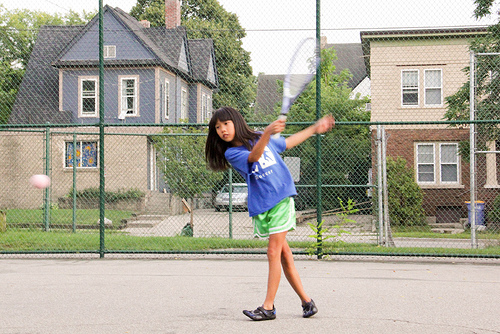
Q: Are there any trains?
A: No, there are no trains.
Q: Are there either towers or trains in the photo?
A: No, there are no trains or towers.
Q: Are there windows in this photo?
A: Yes, there is a window.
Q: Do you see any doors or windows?
A: Yes, there is a window.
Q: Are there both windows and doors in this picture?
A: No, there is a window but no doors.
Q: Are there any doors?
A: No, there are no doors.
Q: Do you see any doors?
A: No, there are no doors.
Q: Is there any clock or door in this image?
A: No, there are no doors or clocks.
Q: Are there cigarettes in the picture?
A: No, there are no cigarettes.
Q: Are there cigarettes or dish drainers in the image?
A: No, there are no cigarettes or dish drainers.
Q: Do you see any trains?
A: No, there are no trains.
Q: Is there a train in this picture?
A: No, there are no trains.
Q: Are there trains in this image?
A: No, there are no trains.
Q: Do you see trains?
A: No, there are no trains.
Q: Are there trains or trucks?
A: No, there are no trains or trucks.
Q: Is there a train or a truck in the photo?
A: No, there are no trains or trucks.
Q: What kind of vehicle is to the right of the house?
A: The vehicle is a car.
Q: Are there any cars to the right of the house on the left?
A: Yes, there is a car to the right of the house.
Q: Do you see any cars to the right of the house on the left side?
A: Yes, there is a car to the right of the house.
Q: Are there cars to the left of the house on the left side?
A: No, the car is to the right of the house.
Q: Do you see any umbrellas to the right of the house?
A: No, there is a car to the right of the house.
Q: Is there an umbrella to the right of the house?
A: No, there is a car to the right of the house.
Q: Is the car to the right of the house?
A: Yes, the car is to the right of the house.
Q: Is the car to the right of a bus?
A: No, the car is to the right of the house.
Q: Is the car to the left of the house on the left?
A: No, the car is to the right of the house.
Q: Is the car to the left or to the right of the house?
A: The car is to the right of the house.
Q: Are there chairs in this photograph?
A: No, there are no chairs.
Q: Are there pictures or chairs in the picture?
A: No, there are no chairs or pictures.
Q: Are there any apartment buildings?
A: No, there are no apartment buildings.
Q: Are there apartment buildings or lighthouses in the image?
A: No, there are no apartment buildings or lighthouses.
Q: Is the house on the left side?
A: Yes, the house is on the left of the image.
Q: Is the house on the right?
A: No, the house is on the left of the image.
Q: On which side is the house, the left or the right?
A: The house is on the left of the image.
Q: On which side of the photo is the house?
A: The house is on the left of the image.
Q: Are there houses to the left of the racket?
A: Yes, there is a house to the left of the racket.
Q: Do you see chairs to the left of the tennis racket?
A: No, there is a house to the left of the tennis racket.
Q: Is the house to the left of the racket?
A: Yes, the house is to the left of the racket.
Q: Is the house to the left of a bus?
A: No, the house is to the left of the racket.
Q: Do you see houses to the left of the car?
A: Yes, there is a house to the left of the car.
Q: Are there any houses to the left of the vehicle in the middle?
A: Yes, there is a house to the left of the car.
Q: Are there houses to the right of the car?
A: No, the house is to the left of the car.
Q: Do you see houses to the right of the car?
A: No, the house is to the left of the car.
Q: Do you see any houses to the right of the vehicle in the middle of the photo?
A: No, the house is to the left of the car.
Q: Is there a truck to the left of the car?
A: No, there is a house to the left of the car.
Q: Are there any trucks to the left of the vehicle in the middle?
A: No, there is a house to the left of the car.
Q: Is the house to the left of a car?
A: Yes, the house is to the left of a car.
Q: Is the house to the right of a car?
A: No, the house is to the left of a car.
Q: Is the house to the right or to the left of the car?
A: The house is to the left of the car.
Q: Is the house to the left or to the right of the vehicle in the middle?
A: The house is to the left of the car.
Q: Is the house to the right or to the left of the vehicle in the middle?
A: The house is to the left of the car.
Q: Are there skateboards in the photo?
A: No, there are no skateboards.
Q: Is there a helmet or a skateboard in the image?
A: No, there are no skateboards or helmets.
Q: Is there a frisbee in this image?
A: No, there are no frisbees.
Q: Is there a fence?
A: Yes, there is a fence.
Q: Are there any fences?
A: Yes, there is a fence.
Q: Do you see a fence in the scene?
A: Yes, there is a fence.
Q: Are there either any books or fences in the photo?
A: Yes, there is a fence.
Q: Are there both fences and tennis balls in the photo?
A: Yes, there are both a fence and a tennis ball.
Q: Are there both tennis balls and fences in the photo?
A: Yes, there are both a fence and a tennis ball.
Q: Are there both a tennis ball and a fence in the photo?
A: Yes, there are both a fence and a tennis ball.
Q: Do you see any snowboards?
A: No, there are no snowboards.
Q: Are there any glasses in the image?
A: No, there are no glasses.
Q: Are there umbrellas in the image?
A: No, there are no umbrellas.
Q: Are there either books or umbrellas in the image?
A: No, there are no umbrellas or books.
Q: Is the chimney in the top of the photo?
A: Yes, the chimney is in the top of the image.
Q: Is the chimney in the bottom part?
A: No, the chimney is in the top of the image.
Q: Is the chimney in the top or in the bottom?
A: The chimney is in the top of the image.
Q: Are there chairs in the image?
A: No, there are no chairs.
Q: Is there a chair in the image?
A: No, there are no chairs.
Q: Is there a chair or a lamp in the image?
A: No, there are no chairs or lamps.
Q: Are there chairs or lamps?
A: No, there are no chairs or lamps.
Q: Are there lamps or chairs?
A: No, there are no chairs or lamps.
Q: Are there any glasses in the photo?
A: No, there are no glasses.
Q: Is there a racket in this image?
A: Yes, there is a racket.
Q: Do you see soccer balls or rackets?
A: Yes, there is a racket.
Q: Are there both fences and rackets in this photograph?
A: Yes, there are both a racket and a fence.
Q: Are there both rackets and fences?
A: Yes, there are both a racket and a fence.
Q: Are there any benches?
A: No, there are no benches.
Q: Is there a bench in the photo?
A: No, there are no benches.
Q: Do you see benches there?
A: No, there are no benches.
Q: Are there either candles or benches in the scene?
A: No, there are no benches or candles.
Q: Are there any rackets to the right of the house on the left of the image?
A: Yes, there is a racket to the right of the house.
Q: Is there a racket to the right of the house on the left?
A: Yes, there is a racket to the right of the house.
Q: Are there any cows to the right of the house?
A: No, there is a racket to the right of the house.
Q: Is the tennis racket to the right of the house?
A: Yes, the tennis racket is to the right of the house.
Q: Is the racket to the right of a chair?
A: No, the racket is to the right of the house.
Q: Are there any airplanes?
A: No, there are no airplanes.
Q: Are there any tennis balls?
A: Yes, there is a tennis ball.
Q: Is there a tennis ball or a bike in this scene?
A: Yes, there is a tennis ball.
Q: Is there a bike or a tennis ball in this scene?
A: Yes, there is a tennis ball.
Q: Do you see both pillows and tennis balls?
A: No, there is a tennis ball but no pillows.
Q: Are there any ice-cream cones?
A: No, there are no ice-cream cones.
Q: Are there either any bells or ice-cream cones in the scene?
A: No, there are no ice-cream cones or bells.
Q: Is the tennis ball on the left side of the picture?
A: Yes, the tennis ball is on the left of the image.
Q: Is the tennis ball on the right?
A: No, the tennis ball is on the left of the image.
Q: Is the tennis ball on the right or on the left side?
A: The tennis ball is on the left of the image.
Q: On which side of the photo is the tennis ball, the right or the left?
A: The tennis ball is on the left of the image.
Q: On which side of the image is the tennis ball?
A: The tennis ball is on the left of the image.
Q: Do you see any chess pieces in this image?
A: No, there are no chess pieces.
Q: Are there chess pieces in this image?
A: No, there are no chess pieces.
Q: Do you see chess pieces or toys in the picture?
A: No, there are no chess pieces or toys.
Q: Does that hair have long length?
A: Yes, the hair is long.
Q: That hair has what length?
A: The hair is long.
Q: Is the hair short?
A: No, the hair is long.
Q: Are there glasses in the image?
A: No, there are no glasses.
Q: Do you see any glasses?
A: No, there are no glasses.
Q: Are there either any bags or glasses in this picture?
A: No, there are no glasses or bags.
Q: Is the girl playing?
A: Yes, the girl is playing.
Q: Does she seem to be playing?
A: Yes, the girl is playing.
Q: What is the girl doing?
A: The girl is playing.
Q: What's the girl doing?
A: The girl is playing.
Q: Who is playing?
A: The girl is playing.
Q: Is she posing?
A: No, the girl is playing.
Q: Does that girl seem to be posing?
A: No, the girl is playing.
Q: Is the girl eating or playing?
A: The girl is playing.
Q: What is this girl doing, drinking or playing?
A: The girl is playing.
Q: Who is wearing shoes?
A: The girl is wearing shoes.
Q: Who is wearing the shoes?
A: The girl is wearing shoes.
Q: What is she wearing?
A: The girl is wearing shoes.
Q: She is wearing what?
A: The girl is wearing shoes.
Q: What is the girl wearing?
A: The girl is wearing shoes.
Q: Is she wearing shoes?
A: Yes, the girl is wearing shoes.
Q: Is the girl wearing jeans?
A: No, the girl is wearing shoes.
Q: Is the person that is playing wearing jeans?
A: No, the girl is wearing shoes.